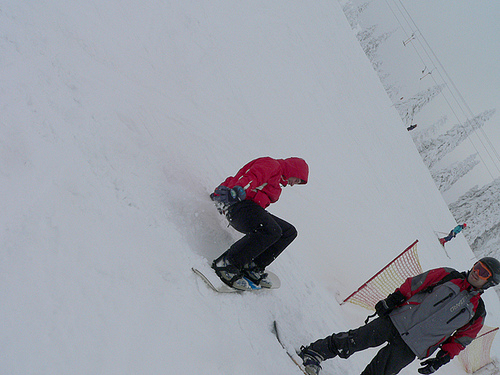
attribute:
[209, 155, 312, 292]
person — snowboarding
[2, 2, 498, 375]
snow — white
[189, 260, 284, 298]
snowboard — white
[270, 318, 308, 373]
snowboard — white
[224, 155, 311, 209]
jacket — pink, red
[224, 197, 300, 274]
pants — black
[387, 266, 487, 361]
coat — grey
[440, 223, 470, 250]
person — skiing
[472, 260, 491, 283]
goggles — orange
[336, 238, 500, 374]
fence — orange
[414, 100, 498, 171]
tree — pine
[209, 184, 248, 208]
glove — gray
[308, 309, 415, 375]
pants — dark grey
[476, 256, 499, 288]
helmet — black